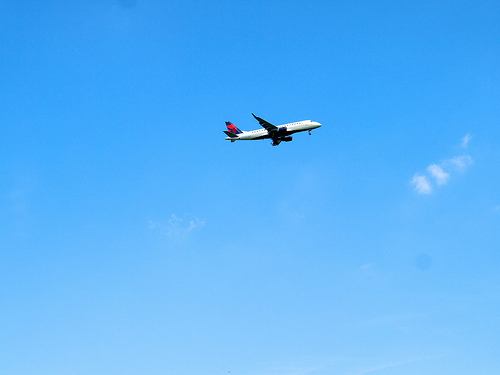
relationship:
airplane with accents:
[223, 112, 320, 146] [219, 121, 244, 141]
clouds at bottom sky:
[411, 112, 475, 200] [1, 4, 498, 364]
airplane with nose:
[223, 112, 320, 146] [296, 110, 325, 130]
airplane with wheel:
[223, 112, 320, 146] [274, 137, 282, 145]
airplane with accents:
[223, 112, 320, 146] [215, 111, 245, 142]